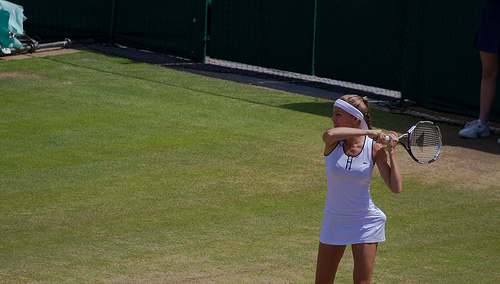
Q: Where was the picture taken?
A: At a tennis match.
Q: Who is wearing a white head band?
A: The woman player.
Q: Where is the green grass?
A: On the tennis court.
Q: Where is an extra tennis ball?
A: In the player's pocket.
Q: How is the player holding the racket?
A: With both hands.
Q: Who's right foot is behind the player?
A: A spectator.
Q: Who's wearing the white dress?
A: The player.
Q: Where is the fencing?
A: Around the court.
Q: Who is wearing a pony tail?
A: The player.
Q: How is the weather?
A: Sunny.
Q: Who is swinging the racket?
A: The woman.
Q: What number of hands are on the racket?
A: Two.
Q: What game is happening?
A: Tennis.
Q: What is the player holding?
A: Racket.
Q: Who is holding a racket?
A: Tennis player.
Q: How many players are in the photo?
A: One.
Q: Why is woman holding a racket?
A: To play tennis.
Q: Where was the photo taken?
A: At a tennis court.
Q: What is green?
A: The court.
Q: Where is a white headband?
A: On woman's head.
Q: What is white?
A: Player's outfit.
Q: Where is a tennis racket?
A: In a woman's hands.